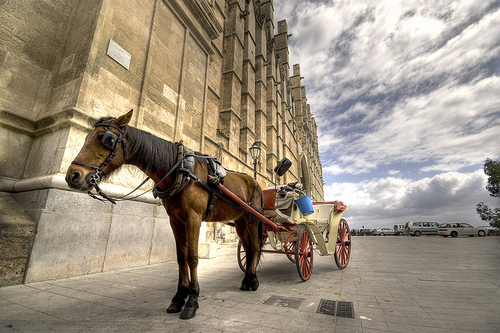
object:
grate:
[315, 296, 355, 319]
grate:
[262, 294, 305, 309]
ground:
[0, 232, 499, 331]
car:
[404, 220, 441, 237]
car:
[437, 221, 488, 237]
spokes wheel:
[335, 218, 352, 269]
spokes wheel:
[295, 230, 314, 281]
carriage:
[235, 157, 352, 282]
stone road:
[4, 223, 495, 331]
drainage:
[316, 297, 355, 319]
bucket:
[294, 196, 314, 217]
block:
[98, 130, 122, 150]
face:
[63, 121, 123, 188]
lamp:
[249, 141, 261, 180]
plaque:
[105, 39, 133, 70]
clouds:
[332, 42, 470, 171]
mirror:
[272, 157, 291, 177]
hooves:
[176, 299, 200, 320]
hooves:
[242, 272, 259, 290]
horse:
[64, 108, 264, 319]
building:
[0, 0, 325, 289]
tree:
[472, 160, 498, 224]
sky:
[306, 2, 496, 209]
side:
[466, 134, 498, 250]